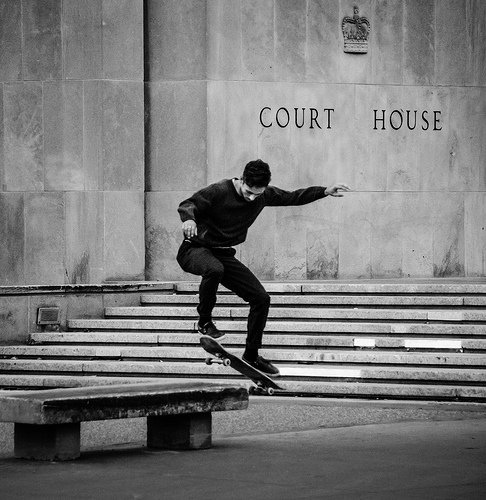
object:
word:
[260, 107, 335, 129]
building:
[1, 1, 484, 343]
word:
[373, 109, 442, 131]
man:
[176, 159, 350, 377]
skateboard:
[200, 335, 287, 395]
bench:
[0, 378, 249, 460]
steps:
[0, 280, 486, 401]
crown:
[342, 6, 370, 54]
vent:
[36, 306, 60, 325]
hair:
[243, 159, 271, 188]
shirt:
[177, 177, 328, 247]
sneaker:
[197, 322, 226, 340]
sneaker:
[242, 355, 280, 376]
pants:
[176, 239, 270, 349]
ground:
[0, 415, 486, 500]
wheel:
[223, 358, 231, 366]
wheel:
[205, 357, 212, 365]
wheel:
[267, 387, 274, 395]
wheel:
[249, 386, 256, 395]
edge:
[249, 371, 287, 396]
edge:
[0, 396, 43, 424]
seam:
[80, 417, 486, 450]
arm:
[265, 183, 351, 207]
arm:
[177, 179, 227, 239]